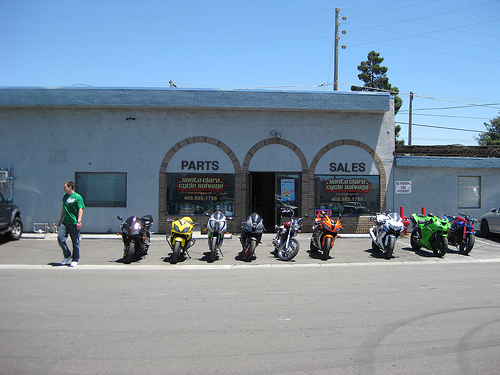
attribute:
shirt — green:
[59, 192, 85, 224]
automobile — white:
[482, 201, 498, 242]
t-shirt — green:
[56, 187, 87, 227]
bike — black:
[118, 210, 154, 262]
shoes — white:
[59, 257, 81, 265]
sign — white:
[178, 153, 228, 175]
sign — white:
[325, 157, 370, 174]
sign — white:
[168, 175, 228, 206]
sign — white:
[323, 176, 374, 207]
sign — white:
[393, 177, 415, 200]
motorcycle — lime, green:
[410, 211, 450, 257]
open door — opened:
[246, 171, 276, 232]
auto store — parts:
[0, 86, 498, 236]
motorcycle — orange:
[308, 202, 345, 264]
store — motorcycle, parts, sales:
[0, 87, 395, 231]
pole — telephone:
[324, 31, 364, 106]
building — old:
[120, 80, 390, 240]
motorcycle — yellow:
[163, 213, 196, 262]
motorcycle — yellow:
[200, 210, 232, 260]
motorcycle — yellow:
[114, 213, 156, 262]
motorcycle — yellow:
[238, 210, 265, 262]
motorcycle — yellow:
[276, 213, 304, 259]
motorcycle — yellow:
[309, 211, 341, 258]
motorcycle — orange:
[286, 182, 366, 275]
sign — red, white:
[393, 177, 416, 196]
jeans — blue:
[57, 222, 81, 262]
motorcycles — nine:
[127, 209, 469, 259]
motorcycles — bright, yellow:
[19, 184, 479, 301]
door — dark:
[255, 149, 307, 227]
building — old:
[0, 68, 410, 263]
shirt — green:
[51, 190, 86, 228]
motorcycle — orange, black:
[311, 211, 340, 265]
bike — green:
[409, 211, 451, 256]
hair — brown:
[65, 178, 78, 192]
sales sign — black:
[327, 159, 367, 173]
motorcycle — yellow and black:
[165, 212, 197, 263]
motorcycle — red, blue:
[441, 213, 481, 255]